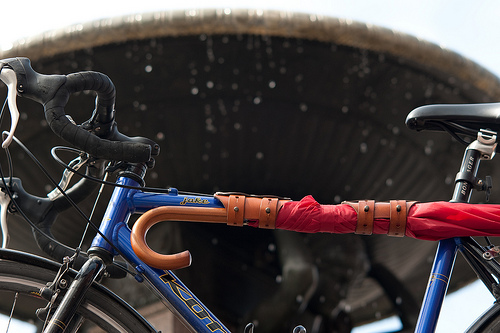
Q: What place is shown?
A: It is a tunnel.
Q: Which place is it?
A: It is a tunnel.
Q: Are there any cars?
A: No, there are no cars.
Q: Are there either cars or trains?
A: No, there are no cars or trains.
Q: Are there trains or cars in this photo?
A: No, there are no cars or trains.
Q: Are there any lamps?
A: No, there are no lamps.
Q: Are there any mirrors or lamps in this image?
A: No, there are no lamps or mirrors.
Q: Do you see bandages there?
A: No, there are no bandages.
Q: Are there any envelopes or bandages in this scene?
A: No, there are no bandages or envelopes.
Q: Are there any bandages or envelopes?
A: No, there are no bandages or envelopes.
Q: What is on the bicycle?
A: The wires are on the bicycle.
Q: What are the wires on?
A: The wires are on the bicycle.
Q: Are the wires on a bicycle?
A: Yes, the wires are on a bicycle.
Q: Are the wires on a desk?
A: No, the wires are on a bicycle.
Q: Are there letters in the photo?
A: Yes, there are letters.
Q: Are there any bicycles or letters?
A: Yes, there are letters.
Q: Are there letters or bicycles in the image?
A: Yes, there are letters.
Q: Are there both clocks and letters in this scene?
A: No, there are letters but no clocks.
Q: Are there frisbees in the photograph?
A: No, there are no frisbees.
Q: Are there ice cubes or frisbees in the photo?
A: No, there are no frisbees or ice cubes.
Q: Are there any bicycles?
A: Yes, there is a bicycle.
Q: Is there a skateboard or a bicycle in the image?
A: Yes, there is a bicycle.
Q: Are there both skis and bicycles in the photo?
A: No, there is a bicycle but no skis.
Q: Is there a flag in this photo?
A: No, there are no flags.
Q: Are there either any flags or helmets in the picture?
A: No, there are no flags or helmets.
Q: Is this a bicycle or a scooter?
A: This is a bicycle.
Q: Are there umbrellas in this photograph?
A: Yes, there is an umbrella.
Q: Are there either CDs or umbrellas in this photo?
A: Yes, there is an umbrella.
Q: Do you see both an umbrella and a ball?
A: No, there is an umbrella but no balls.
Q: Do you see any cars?
A: No, there are no cars.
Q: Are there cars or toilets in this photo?
A: No, there are no cars or toilets.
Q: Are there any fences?
A: No, there are no fences.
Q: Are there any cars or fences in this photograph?
A: No, there are no fences or cars.